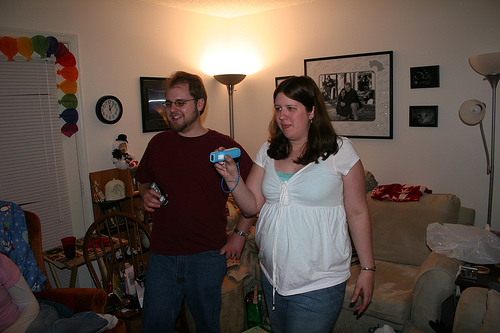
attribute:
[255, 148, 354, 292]
shirt — white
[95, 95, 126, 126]
clock — black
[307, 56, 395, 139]
picture — black, white, framed, matted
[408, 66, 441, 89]
picture — black, framed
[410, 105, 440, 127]
picture — small, black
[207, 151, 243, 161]
remote — blue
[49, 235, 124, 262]
folding table — small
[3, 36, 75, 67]
decorative cut out — balloons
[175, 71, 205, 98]
hair — brown, short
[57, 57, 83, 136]
balloons — colorful